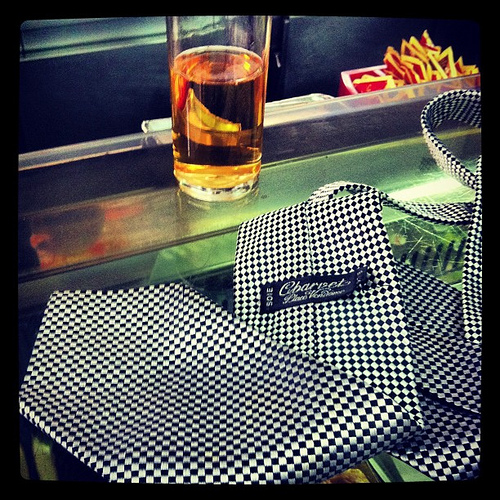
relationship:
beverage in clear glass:
[170, 49, 262, 192] [164, 15, 273, 206]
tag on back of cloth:
[256, 265, 368, 317] [19, 87, 478, 497]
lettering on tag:
[276, 277, 349, 307] [256, 265, 368, 317]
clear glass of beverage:
[164, 15, 273, 206] [170, 49, 262, 192]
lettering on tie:
[278, 279, 352, 296] [239, 181, 370, 359]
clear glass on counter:
[164, 15, 273, 206] [17, 69, 478, 479]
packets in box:
[350, 30, 458, 77] [337, 63, 480, 107]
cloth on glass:
[19, 87, 478, 497] [17, 127, 481, 482]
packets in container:
[338, 30, 478, 106] [333, 58, 408, 97]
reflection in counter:
[23, 194, 149, 267] [17, 69, 478, 479]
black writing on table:
[402, 238, 464, 272] [16, 72, 481, 480]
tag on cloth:
[256, 265, 368, 317] [19, 87, 478, 497]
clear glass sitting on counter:
[164, 15, 273, 206] [29, 128, 482, 258]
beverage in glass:
[170, 49, 262, 192] [169, 9, 289, 209]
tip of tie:
[47, 284, 65, 304] [19, 190, 424, 483]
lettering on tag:
[278, 279, 352, 296] [254, 261, 375, 313]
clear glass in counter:
[164, 15, 273, 206] [17, 69, 478, 479]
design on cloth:
[158, 364, 181, 385] [36, 157, 486, 498]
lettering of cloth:
[278, 279, 352, 296] [19, 87, 478, 497]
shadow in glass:
[176, 85, 256, 165] [170, 13, 277, 202]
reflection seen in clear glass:
[178, 65, 235, 148] [164, 15, 273, 206]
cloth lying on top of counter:
[19, 87, 478, 497] [17, 69, 478, 479]